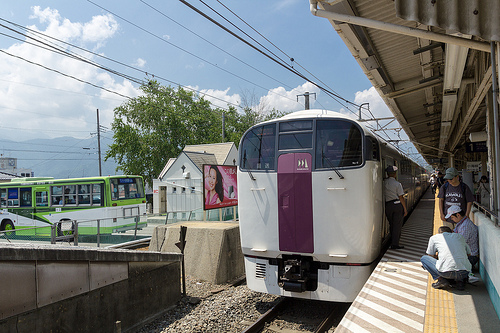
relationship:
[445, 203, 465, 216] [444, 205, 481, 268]
hat on man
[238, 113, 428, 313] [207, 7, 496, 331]
train parked at station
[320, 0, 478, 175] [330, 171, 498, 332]
overhang on platform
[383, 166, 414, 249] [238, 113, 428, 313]
driver checking train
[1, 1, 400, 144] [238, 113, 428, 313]
lines above train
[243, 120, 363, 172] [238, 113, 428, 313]
windshield on train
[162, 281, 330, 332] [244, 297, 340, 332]
gravel covering between train rails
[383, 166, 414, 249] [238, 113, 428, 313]
driver leaning on train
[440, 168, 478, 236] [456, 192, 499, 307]
man leaning on wall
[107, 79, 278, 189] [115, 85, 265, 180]
tree has leaves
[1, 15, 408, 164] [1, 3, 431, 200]
clouds in sky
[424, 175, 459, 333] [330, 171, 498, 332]
stripe painted on platform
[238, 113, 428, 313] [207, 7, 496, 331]
train stopped at station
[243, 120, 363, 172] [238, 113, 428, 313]
windshield of train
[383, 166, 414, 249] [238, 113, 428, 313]
driver standing next to train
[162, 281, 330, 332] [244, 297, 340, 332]
gravel around train rails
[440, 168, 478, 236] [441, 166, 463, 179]
man wearing hat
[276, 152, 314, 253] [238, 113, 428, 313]
door on train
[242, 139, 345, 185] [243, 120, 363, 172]
windshield wiper on windshield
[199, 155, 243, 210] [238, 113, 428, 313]
billboard by train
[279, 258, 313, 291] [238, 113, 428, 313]
connector on train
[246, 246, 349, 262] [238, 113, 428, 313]
handle bar on train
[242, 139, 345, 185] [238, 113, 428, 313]
windshield wiper on front of train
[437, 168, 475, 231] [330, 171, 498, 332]
man standing on platform